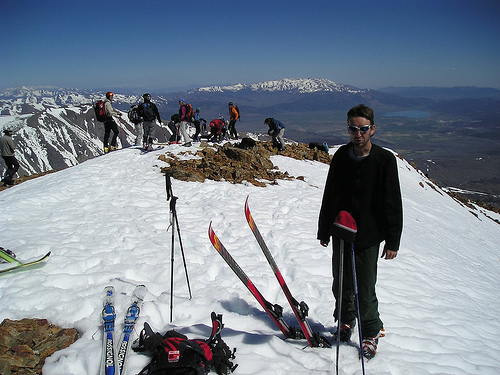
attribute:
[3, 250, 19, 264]
ski — green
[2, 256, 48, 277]
ski — green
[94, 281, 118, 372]
ski — blue, white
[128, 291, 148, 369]
ski — blue, white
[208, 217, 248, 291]
ski — red, orange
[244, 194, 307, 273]
ski — red, orange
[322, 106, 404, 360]
man — posing, standing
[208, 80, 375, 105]
mountain — snow capped, tall, rocky, covered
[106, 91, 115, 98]
helmet — orange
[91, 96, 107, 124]
backpack — red, black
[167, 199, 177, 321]
ski pole — vertical, grey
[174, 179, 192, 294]
ski pole — vertical, grey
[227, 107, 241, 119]
jacket — orange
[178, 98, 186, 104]
hat — blue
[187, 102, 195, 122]
backpack — red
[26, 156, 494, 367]
snow — white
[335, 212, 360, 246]
hat — red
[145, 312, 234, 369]
backpack — red, black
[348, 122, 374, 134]
ski goggles — silver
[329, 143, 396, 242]
coat — black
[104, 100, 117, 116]
jacket — grey